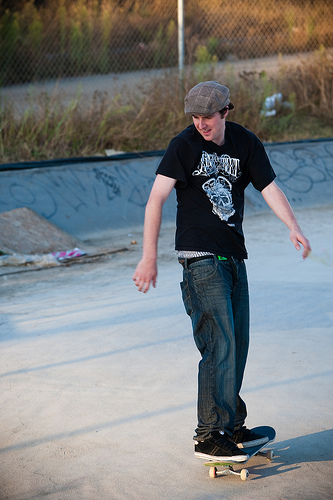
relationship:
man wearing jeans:
[130, 74, 313, 462] [175, 246, 258, 437]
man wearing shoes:
[130, 74, 313, 462] [192, 410, 262, 462]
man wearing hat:
[130, 74, 313, 462] [177, 74, 239, 121]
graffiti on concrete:
[6, 145, 330, 222] [0, 132, 330, 252]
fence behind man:
[2, 0, 326, 107] [130, 74, 313, 462]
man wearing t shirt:
[130, 74, 313, 462] [152, 134, 268, 260]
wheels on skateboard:
[206, 448, 277, 487] [193, 422, 282, 480]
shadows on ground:
[257, 416, 332, 481] [5, 202, 332, 497]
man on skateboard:
[130, 74, 313, 462] [193, 422, 282, 480]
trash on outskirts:
[257, 89, 290, 122] [2, 130, 332, 132]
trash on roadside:
[257, 89, 290, 122] [0, 59, 329, 178]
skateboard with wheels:
[193, 422, 282, 480] [206, 448, 277, 487]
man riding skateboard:
[130, 74, 313, 462] [193, 422, 282, 480]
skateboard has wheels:
[193, 422, 282, 480] [206, 448, 277, 487]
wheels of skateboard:
[206, 448, 277, 487] [193, 422, 282, 480]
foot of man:
[194, 430, 250, 465] [130, 74, 313, 462]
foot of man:
[224, 421, 267, 446] [130, 74, 313, 462]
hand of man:
[130, 254, 160, 293] [130, 74, 313, 462]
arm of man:
[252, 148, 313, 255] [130, 74, 313, 462]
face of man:
[188, 112, 222, 144] [130, 74, 313, 462]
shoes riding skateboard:
[192, 410, 262, 462] [193, 422, 282, 480]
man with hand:
[130, 74, 313, 462] [130, 254, 160, 293]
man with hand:
[130, 74, 313, 462] [279, 226, 318, 259]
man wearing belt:
[130, 74, 313, 462] [183, 252, 248, 265]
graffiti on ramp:
[3, 136, 331, 218] [6, 145, 330, 222]